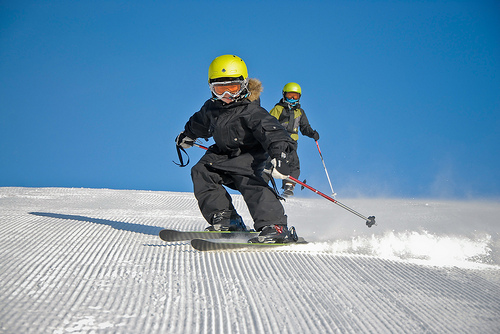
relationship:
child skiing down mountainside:
[174, 55, 297, 244] [1, 175, 498, 332]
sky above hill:
[6, 1, 492, 199] [0, 186, 500, 333]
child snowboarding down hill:
[150, 47, 321, 258] [16, 183, 456, 290]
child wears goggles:
[174, 55, 297, 244] [208, 80, 248, 98]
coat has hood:
[171, 79, 309, 248] [241, 78, 265, 103]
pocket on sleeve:
[258, 112, 285, 138] [265, 109, 302, 188]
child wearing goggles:
[181, 62, 304, 251] [209, 76, 249, 105]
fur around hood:
[241, 76, 269, 101] [230, 67, 274, 108]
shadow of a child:
[26, 208, 165, 235] [174, 55, 297, 244]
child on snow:
[174, 55, 297, 244] [2, 185, 499, 332]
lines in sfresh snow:
[26, 200, 460, 322] [272, 227, 497, 268]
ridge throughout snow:
[39, 221, 46, 326] [0, 229, 490, 331]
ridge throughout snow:
[92, 242, 101, 332] [0, 229, 490, 331]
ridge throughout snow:
[128, 264, 134, 331] [0, 229, 490, 331]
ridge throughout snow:
[222, 259, 237, 332] [0, 229, 490, 331]